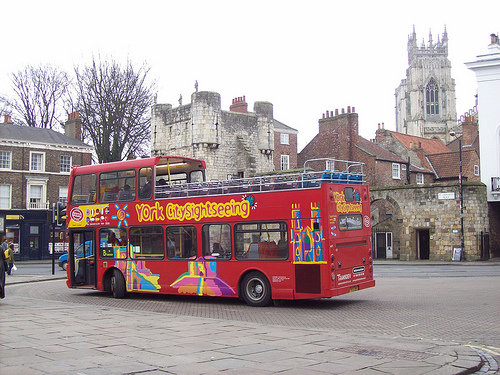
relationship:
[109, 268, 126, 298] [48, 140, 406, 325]
front wheel on side of bus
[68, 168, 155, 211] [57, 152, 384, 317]
windows on side of bus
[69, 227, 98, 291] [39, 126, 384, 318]
access door on side of bus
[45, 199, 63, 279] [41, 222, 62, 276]
traffic light on pole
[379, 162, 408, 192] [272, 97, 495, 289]
window in front of building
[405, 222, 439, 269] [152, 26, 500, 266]
door in front of building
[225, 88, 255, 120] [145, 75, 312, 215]
chimney on top of building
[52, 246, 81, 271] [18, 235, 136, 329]
car on street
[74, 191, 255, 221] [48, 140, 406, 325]
sign on bus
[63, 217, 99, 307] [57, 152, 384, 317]
access door on bus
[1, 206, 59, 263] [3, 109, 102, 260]
front door on building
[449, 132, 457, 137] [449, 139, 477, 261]
street light on pole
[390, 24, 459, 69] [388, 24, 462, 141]
tower on buildling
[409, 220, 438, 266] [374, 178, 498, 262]
door on building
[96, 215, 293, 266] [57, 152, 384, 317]
windows are on bus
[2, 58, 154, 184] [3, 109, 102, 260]
trees are by building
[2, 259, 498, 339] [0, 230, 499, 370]
pavers are cover street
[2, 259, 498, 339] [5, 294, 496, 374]
pavers are cover sidewalk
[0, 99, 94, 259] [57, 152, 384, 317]
building in front of bus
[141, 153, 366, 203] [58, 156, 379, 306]
deck on bus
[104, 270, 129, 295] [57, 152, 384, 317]
tire on bus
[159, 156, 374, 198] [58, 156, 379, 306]
rail on bus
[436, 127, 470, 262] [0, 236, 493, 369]
street light on sidewalk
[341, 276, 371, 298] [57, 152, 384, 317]
license plate on bus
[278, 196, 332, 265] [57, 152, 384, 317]
castle painted on bus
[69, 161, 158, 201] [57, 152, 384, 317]
windows are on bus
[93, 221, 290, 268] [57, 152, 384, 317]
windows are on bus